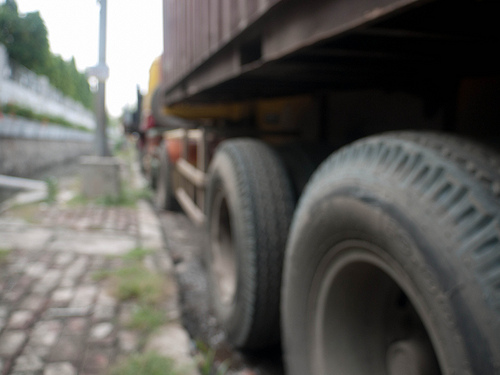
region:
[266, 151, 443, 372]
Black rubber tire on track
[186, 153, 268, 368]
Black rubber tire on track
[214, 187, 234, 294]
dark hub cap on truck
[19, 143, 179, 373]
brick sidewalk by truck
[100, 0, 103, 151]
metal light pole on side walk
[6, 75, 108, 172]
white wall on left of side walk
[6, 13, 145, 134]
tall trees on left of wall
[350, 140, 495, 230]
treads on tire for traction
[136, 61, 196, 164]
yellow and red cab of truck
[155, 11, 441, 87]
metal container on truck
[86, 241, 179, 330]
blurred grass in the pavement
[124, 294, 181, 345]
blurred grass in the pavement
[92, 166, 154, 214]
blurred grass in the pavement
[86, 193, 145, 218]
blurred grass in the pavement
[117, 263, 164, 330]
blurred grass in the pavement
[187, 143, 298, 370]
the tire is gray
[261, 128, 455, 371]
the tire is gray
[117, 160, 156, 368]
green grass growing on sidewalk cracks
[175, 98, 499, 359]
two large black tires on truck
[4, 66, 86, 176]
stone wall along sidewalk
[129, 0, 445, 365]
large truck parked on the side of the road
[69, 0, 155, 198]
silver pole with a concrete base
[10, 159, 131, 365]
red brick sidewalk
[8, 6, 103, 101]
bushes on top of the sidewalk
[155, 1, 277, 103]
metal top of truck brown in color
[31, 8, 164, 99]
bright sky seen in the background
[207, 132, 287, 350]
blurry tire on truck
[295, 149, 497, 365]
blurry front tire on truck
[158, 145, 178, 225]
really blurry tire on truck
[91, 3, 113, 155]
metal light pole in cement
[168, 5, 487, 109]
bottom of dump truck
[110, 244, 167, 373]
weeds growing through sidewalk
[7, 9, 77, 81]
trees off in distance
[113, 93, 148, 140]
blurry black and red truck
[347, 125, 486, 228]
rubber tread on tire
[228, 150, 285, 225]
grooves in the rubber tire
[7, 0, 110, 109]
green trees behind brick wall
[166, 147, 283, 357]
black wheel on ground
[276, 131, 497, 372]
black wheel on ground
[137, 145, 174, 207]
black wheel on ground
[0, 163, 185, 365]
brick walkway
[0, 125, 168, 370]
brick walkway on side of street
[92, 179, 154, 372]
grass growing through brick walkway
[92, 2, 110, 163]
pole on walkway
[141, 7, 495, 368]
truck on side of street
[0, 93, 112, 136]
greenery growing through brick wall